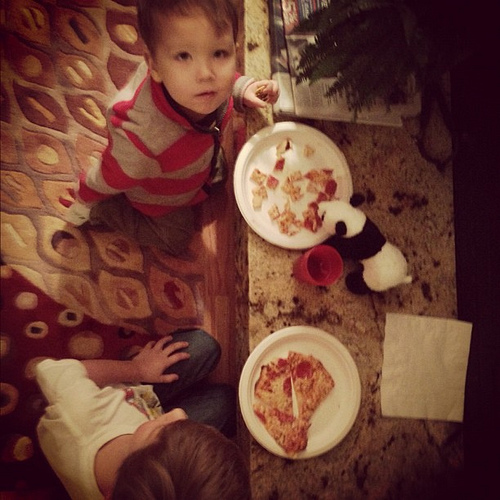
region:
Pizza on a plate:
[234, 323, 366, 464]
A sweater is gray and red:
[59, 63, 257, 228]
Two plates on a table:
[230, 117, 368, 467]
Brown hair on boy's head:
[133, 0, 244, 122]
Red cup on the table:
[286, 241, 347, 293]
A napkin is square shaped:
[373, 308, 475, 426]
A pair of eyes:
[168, 44, 235, 66]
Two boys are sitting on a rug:
[2, 3, 252, 495]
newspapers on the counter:
[270, 2, 410, 122]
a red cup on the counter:
[296, 245, 331, 286]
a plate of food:
[245, 136, 340, 241]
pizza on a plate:
[256, 355, 326, 445]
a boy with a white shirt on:
[45, 345, 246, 495]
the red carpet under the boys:
[1, 0, 242, 495]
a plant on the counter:
[290, 0, 445, 115]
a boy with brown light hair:
[134, 4, 241, 114]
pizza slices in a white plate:
[253, 353, 333, 459]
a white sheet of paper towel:
[381, 313, 473, 424]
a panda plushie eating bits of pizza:
[316, 192, 413, 293]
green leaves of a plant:
[289, 0, 437, 126]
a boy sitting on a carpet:
[58, 3, 278, 253]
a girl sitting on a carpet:
[36, 326, 248, 498]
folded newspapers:
[272, 3, 421, 130]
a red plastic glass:
[292, 245, 345, 286]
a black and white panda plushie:
[314, 191, 414, 296]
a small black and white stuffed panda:
[311, 190, 413, 296]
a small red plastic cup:
[293, 247, 343, 287]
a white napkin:
[380, 304, 471, 421]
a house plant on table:
[289, 2, 474, 123]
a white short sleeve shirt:
[34, 360, 166, 499]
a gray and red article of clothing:
[67, 67, 242, 214]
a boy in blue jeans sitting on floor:
[33, 325, 238, 499]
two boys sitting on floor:
[34, 0, 280, 497]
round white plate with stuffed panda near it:
[229, 120, 343, 250]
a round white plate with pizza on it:
[239, 322, 360, 462]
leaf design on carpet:
[94, 263, 149, 321]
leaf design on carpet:
[45, 267, 111, 326]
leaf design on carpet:
[36, 213, 91, 271]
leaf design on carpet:
[85, 228, 145, 276]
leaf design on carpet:
[0, 211, 49, 273]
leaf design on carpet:
[1, 170, 50, 207]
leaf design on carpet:
[41, 175, 82, 219]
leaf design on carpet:
[13, 78, 69, 136]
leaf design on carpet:
[60, 48, 109, 96]